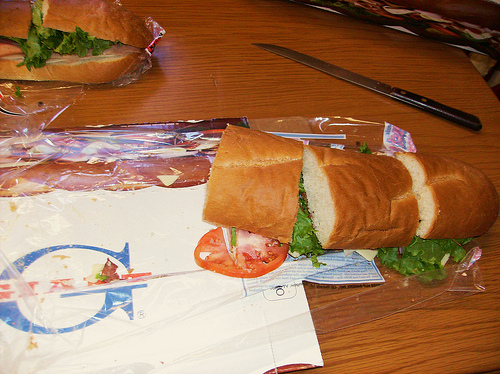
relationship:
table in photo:
[213, 51, 240, 95] [4, 4, 497, 344]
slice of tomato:
[226, 236, 270, 265] [183, 218, 295, 288]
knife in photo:
[245, 28, 489, 135] [4, 4, 497, 344]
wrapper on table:
[349, 292, 413, 323] [213, 51, 240, 95]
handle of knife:
[393, 82, 484, 134] [245, 28, 489, 135]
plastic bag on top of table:
[309, 114, 364, 131] [213, 51, 240, 95]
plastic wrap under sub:
[207, 116, 396, 134] [199, 113, 499, 248]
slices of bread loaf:
[216, 126, 420, 253] [42, 10, 168, 42]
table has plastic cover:
[213, 51, 240, 95] [5, 85, 50, 120]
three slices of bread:
[216, 126, 420, 253] [431, 2, 496, 19]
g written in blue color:
[4, 229, 152, 343] [81, 244, 99, 253]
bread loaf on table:
[0, 0, 151, 86] [213, 51, 240, 95]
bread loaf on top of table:
[0, 0, 151, 86] [213, 51, 240, 95]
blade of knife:
[250, 33, 384, 103] [245, 28, 489, 135]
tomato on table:
[183, 218, 295, 288] [213, 51, 240, 95]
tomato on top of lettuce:
[183, 218, 295, 288] [396, 244, 440, 275]